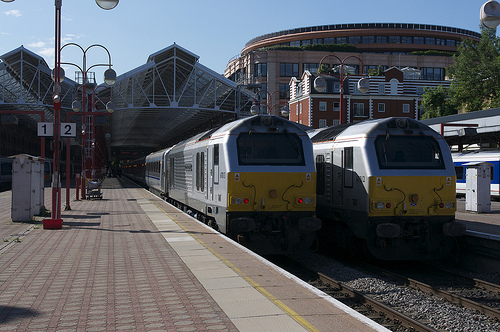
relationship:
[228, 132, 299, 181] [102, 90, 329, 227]
windshield of train